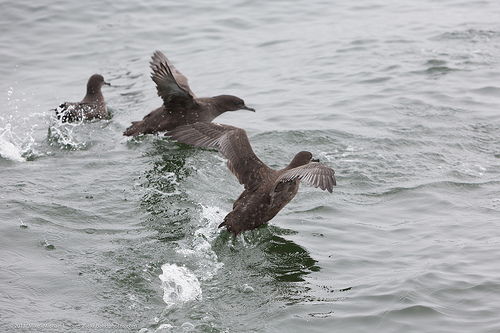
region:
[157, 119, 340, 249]
a dark feathered bird in water.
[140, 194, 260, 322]
foamy water behind a bird.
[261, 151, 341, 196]
the right wing of a bird.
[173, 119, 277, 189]
the left wing of a bird.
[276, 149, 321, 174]
a bird head.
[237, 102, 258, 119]
a long bird beak.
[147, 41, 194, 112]
a wing on a bird.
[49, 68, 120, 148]
a bird swimming in water.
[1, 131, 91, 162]
splash created by a bird.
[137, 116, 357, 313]
a bird splashing in the water.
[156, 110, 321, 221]
the bird is about to fly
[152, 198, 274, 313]
the bird is making waves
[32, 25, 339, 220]
three birds are in the water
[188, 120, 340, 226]
the bird is brown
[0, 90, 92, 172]
the water is in motion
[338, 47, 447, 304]
the water is grey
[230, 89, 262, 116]
the birds beak is curved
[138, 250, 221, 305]
the water is white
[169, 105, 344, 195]
the wings are light grey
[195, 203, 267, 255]
the birds feet are in the water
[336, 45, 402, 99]
part of a water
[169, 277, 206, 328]
part of a splash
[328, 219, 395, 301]
part of a water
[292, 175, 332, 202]
edge of a wing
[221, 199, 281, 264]
part of a tail wing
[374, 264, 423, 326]
part of a water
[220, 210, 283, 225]
edge of a bird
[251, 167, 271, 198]
back of a bird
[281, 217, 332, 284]
edge of a shadow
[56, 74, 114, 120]
bird swimming in the water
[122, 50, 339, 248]
two birds are above the water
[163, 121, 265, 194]
wing of bird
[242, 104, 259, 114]
beak of bird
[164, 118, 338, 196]
the bird's wings are outstretched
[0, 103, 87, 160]
water splashing behind bird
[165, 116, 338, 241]
bird is brownish-gray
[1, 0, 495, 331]
water under three birds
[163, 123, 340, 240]
bird splashing in water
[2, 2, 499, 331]
water is gray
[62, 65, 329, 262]
these are three birds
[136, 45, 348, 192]
the bird's wings are stretched out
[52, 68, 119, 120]
the bird is sitting on the water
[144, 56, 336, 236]
the two birds are about to fly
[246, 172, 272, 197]
the feathers are brown in color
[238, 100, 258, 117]
this is a beak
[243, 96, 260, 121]
the beak is sharp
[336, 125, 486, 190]
there are ripples of water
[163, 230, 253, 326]
the water is moved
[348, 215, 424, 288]
the water is blue in color